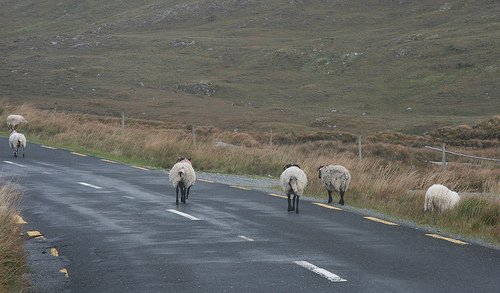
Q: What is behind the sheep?
A: A hill.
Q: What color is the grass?
A: Brown.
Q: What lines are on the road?
A: Dashes.